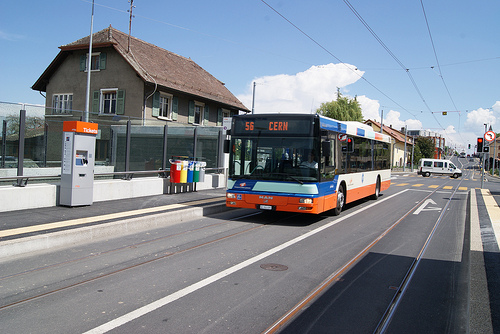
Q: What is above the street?
A: Wires.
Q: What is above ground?
A: Power lines/cables.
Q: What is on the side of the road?
A: A building.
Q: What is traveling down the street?
A: A bus.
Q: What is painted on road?
A: White lines.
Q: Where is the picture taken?
A: A bus stop.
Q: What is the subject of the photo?
A: Bus.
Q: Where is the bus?
A: Street.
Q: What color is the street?
A: Gray.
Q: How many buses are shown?
A: One.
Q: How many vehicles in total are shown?
A: Two.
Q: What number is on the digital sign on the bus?
A: Fifty six.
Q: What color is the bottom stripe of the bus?
A: Orange.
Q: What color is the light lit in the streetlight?
A: Red.